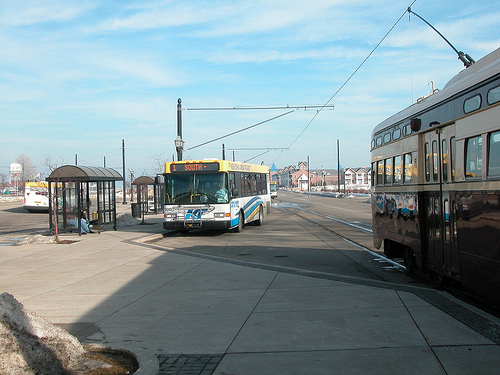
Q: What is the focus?
A: Bus stop and a trolley.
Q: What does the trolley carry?
A: People.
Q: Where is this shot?
A: Trolley stop.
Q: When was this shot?
A: Daytime.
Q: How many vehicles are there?
A: 2.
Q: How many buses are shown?
A: 1.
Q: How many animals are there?
A: 0.